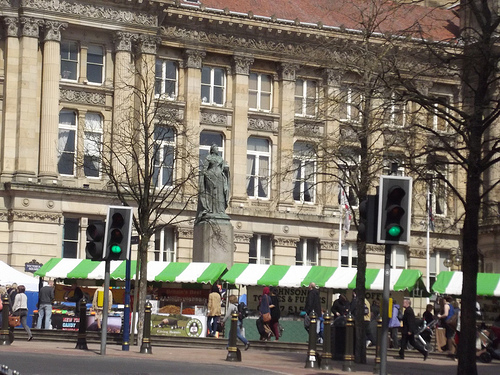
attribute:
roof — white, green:
[215, 256, 429, 296]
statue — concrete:
[192, 136, 240, 205]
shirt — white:
[12, 290, 32, 306]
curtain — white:
[83, 107, 107, 166]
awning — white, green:
[37, 250, 419, 299]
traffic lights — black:
[383, 178, 412, 242]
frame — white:
[363, 158, 423, 253]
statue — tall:
[194, 139, 251, 269]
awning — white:
[0, 256, 40, 306]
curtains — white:
[243, 134, 273, 191]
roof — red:
[248, 6, 474, 46]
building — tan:
[138, 16, 456, 297]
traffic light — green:
[371, 169, 415, 248]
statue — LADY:
[191, 140, 232, 220]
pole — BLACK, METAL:
[221, 310, 245, 363]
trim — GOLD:
[230, 310, 240, 320]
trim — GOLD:
[223, 341, 241, 352]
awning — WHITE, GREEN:
[32, 254, 226, 288]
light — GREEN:
[385, 223, 405, 240]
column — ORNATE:
[39, 17, 68, 184]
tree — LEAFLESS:
[80, 42, 228, 351]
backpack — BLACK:
[237, 297, 248, 321]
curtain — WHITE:
[86, 119, 98, 173]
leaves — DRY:
[295, 28, 377, 209]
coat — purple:
[384, 305, 405, 331]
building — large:
[9, 4, 498, 282]